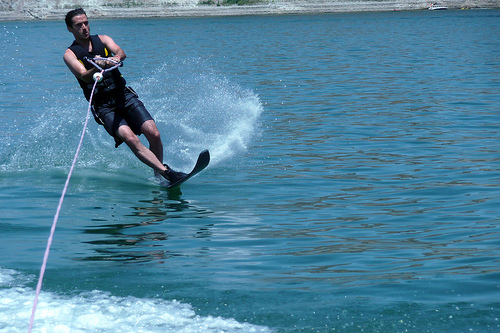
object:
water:
[0, 9, 500, 333]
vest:
[66, 33, 127, 102]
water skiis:
[167, 148, 213, 187]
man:
[64, 7, 189, 186]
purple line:
[27, 75, 102, 333]